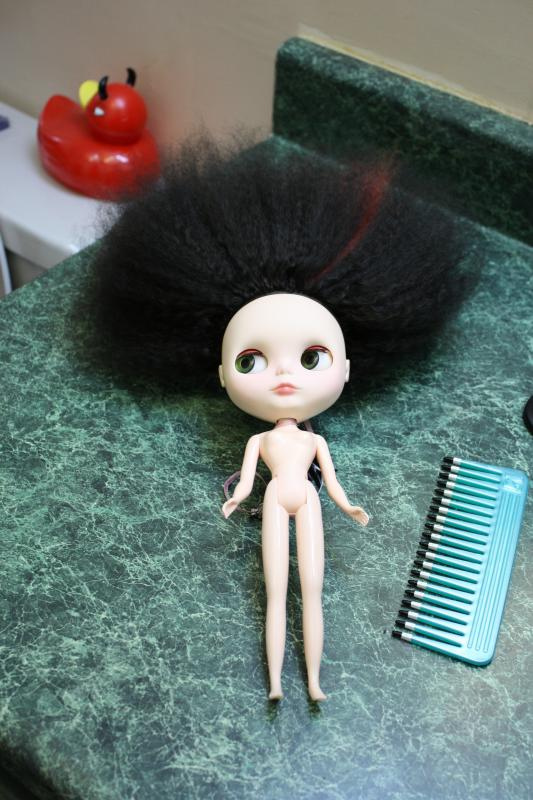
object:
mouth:
[268, 380, 303, 395]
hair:
[53, 129, 494, 426]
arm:
[316, 430, 370, 531]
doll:
[63, 113, 503, 716]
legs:
[259, 501, 292, 705]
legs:
[294, 494, 328, 703]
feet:
[268, 682, 284, 702]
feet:
[307, 682, 328, 703]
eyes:
[229, 343, 272, 380]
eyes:
[295, 342, 342, 379]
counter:
[2, 32, 531, 796]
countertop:
[1, 132, 531, 795]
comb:
[389, 457, 530, 670]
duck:
[32, 66, 166, 205]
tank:
[4, 103, 137, 293]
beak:
[76, 80, 102, 106]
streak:
[324, 162, 395, 276]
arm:
[223, 433, 257, 522]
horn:
[121, 66, 135, 89]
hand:
[346, 503, 370, 528]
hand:
[218, 496, 240, 518]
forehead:
[233, 294, 342, 338]